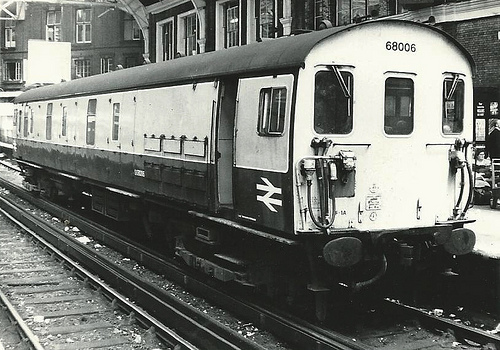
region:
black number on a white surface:
[385, 37, 419, 56]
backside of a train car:
[290, 15, 480, 238]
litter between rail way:
[52, 216, 121, 265]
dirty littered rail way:
[2, 228, 146, 347]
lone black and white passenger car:
[10, 45, 484, 272]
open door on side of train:
[212, 73, 241, 215]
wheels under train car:
[162, 225, 308, 308]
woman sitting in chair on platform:
[475, 148, 492, 202]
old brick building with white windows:
[9, 8, 125, 70]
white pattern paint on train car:
[252, 173, 282, 218]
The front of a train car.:
[287, 18, 482, 282]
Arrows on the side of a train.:
[246, 170, 296, 228]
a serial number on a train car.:
[378, 33, 434, 59]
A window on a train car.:
[300, 40, 371, 150]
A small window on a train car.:
[376, 60, 427, 154]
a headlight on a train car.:
[446, 142, 469, 173]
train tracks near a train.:
[0, 196, 244, 348]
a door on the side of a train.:
[197, 63, 254, 228]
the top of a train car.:
[19, 9, 478, 100]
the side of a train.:
[130, 120, 212, 162]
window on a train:
[437, 73, 467, 143]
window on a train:
[377, 73, 417, 143]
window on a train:
[311, 68, 360, 142]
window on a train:
[253, 83, 290, 143]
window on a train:
[106, 98, 126, 146]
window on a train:
[80, 93, 100, 150]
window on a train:
[59, 104, 69, 143]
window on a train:
[41, 100, 54, 144]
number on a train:
[410, 40, 417, 52]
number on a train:
[384, 39, 394, 49]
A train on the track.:
[23, 60, 469, 265]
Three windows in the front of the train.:
[314, 58, 471, 148]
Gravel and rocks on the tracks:
[57, 223, 164, 343]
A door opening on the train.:
[195, 65, 249, 224]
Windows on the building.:
[139, 21, 298, 55]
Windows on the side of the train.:
[33, 95, 150, 133]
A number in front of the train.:
[373, 30, 422, 57]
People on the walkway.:
[472, 115, 499, 199]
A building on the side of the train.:
[96, 7, 498, 233]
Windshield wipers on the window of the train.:
[323, 47, 360, 103]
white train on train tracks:
[15, 21, 470, 284]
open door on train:
[200, 76, 252, 211]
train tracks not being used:
[0, 184, 200, 348]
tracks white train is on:
[0, 141, 498, 343]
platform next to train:
[452, 195, 498, 296]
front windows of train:
[313, 65, 463, 133]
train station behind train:
[133, 4, 498, 181]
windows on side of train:
[17, 97, 119, 152]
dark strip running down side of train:
[11, 134, 289, 229]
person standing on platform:
[481, 117, 498, 189]